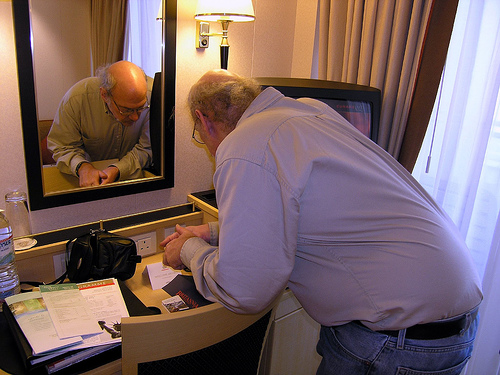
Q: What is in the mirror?
A: The man's reflection.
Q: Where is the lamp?
A: Next to the mirror.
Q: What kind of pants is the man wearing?
A: Blue jeans.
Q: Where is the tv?
A: In the corner.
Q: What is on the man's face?
A: Glasses.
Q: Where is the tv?
A: Behind the man.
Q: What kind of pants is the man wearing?
A: Blue jeans.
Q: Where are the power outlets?
A: On the desk.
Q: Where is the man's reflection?
A: In the mirror.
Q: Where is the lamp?
A: Beside the mirror.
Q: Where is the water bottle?
A: On the desk.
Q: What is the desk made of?
A: Wood.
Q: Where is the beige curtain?
A: Behind the tv.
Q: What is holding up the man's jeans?
A: A belt.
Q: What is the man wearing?
A: Button down shirt.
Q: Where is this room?
A: Hotel.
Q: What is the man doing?
A: Looking down at desk.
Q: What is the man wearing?
A: Jeans and long sleeve shirt.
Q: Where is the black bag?
A: On desk.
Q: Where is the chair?
A: Pushed into desk.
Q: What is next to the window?
A: Tv.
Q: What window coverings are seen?
A: Curtains.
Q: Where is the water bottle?
A: Left side of desk.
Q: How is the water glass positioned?
A: Upside down.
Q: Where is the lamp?
A: Wall next to mirror.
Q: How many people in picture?
A: One.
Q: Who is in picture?
A: A man.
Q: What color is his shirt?
A: Blue.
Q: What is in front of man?
A: A mirror.